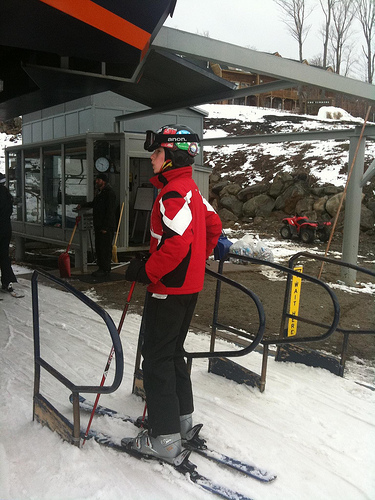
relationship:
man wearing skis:
[121, 123, 229, 462] [62, 394, 277, 499]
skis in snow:
[62, 394, 277, 499] [0, 277, 374, 491]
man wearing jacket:
[121, 123, 229, 462] [141, 162, 223, 296]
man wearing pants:
[121, 123, 229, 462] [136, 291, 200, 433]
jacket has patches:
[141, 162, 223, 296] [145, 190, 194, 284]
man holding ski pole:
[121, 123, 229, 462] [77, 257, 145, 456]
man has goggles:
[121, 123, 229, 462] [139, 127, 202, 150]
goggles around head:
[139, 127, 202, 150] [144, 120, 202, 180]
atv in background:
[280, 212, 330, 241] [2, 3, 374, 311]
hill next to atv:
[203, 132, 373, 258] [280, 212, 330, 241]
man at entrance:
[121, 123, 222, 462] [31, 253, 271, 436]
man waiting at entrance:
[121, 123, 222, 462] [31, 253, 271, 436]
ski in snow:
[51, 416, 240, 500] [0, 277, 374, 491]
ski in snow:
[62, 394, 277, 499] [0, 277, 374, 491]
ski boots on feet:
[129, 412, 197, 461] [128, 416, 194, 456]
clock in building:
[95, 153, 111, 177] [8, 86, 209, 272]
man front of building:
[73, 166, 124, 288] [8, 86, 209, 272]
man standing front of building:
[73, 166, 124, 288] [8, 86, 209, 272]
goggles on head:
[139, 127, 202, 150] [144, 120, 202, 180]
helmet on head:
[153, 121, 204, 153] [144, 120, 202, 180]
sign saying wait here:
[284, 253, 309, 337] [291, 273, 299, 334]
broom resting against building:
[110, 197, 127, 265] [8, 86, 209, 272]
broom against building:
[110, 197, 127, 265] [8, 86, 209, 272]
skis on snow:
[62, 394, 277, 499] [0, 277, 374, 491]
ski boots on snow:
[129, 412, 197, 461] [0, 277, 374, 491]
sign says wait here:
[284, 253, 309, 337] [291, 273, 299, 334]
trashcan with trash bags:
[213, 233, 234, 264] [228, 233, 278, 266]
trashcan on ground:
[213, 233, 234, 264] [5, 227, 374, 492]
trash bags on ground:
[228, 233, 278, 266] [5, 227, 374, 492]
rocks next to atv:
[210, 151, 374, 260] [280, 212, 330, 241]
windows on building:
[25, 147, 86, 220] [8, 107, 209, 272]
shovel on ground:
[56, 215, 81, 277] [5, 227, 374, 492]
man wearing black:
[73, 166, 124, 288] [90, 188, 118, 273]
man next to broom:
[73, 166, 124, 288] [110, 197, 127, 265]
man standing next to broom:
[73, 166, 124, 288] [110, 197, 127, 265]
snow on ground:
[0, 277, 374, 491] [5, 227, 374, 492]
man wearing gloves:
[121, 123, 222, 462] [123, 256, 149, 287]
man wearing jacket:
[121, 123, 222, 462] [141, 162, 223, 296]